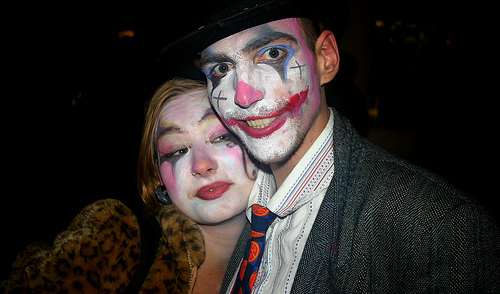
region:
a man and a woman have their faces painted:
[103, 11, 387, 228]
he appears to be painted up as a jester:
[180, 14, 334, 165]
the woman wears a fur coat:
[11, 188, 203, 293]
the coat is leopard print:
[16, 192, 206, 290]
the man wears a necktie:
[228, 203, 275, 292]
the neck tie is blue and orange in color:
[223, 206, 285, 292]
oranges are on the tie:
[235, 218, 278, 292]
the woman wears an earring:
[139, 177, 169, 214]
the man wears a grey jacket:
[293, 133, 492, 290]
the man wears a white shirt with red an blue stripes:
[247, 164, 327, 292]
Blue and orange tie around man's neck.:
[247, 206, 277, 282]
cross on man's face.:
[290, 55, 308, 83]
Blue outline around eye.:
[252, 23, 301, 83]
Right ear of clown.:
[313, 25, 345, 85]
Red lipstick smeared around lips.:
[235, 103, 303, 138]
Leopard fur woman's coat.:
[93, 196, 137, 263]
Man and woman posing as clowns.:
[137, 15, 352, 229]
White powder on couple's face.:
[149, 12, 313, 225]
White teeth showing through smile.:
[239, 109, 284, 136]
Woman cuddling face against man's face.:
[139, 15, 336, 227]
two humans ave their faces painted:
[1, 2, 498, 292]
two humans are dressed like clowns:
[1, 3, 498, 288]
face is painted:
[195, 16, 325, 163]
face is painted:
[148, 86, 253, 225]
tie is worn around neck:
[235, 204, 276, 293]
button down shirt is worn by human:
[228, 106, 343, 292]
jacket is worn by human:
[228, 115, 498, 292]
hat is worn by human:
[168, 0, 303, 64]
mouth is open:
[232, 111, 283, 132]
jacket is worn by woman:
[3, 189, 208, 292]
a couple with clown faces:
[19, 0, 482, 288]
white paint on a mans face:
[204, 15, 315, 171]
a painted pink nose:
[226, 79, 262, 114]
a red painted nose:
[228, 87, 315, 140]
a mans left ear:
[317, 32, 343, 79]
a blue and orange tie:
[231, 202, 281, 289]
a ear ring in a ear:
[151, 182, 173, 208]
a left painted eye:
[259, 38, 291, 74]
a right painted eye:
[210, 52, 236, 87]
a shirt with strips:
[288, 146, 333, 203]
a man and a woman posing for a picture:
[123, 3, 389, 268]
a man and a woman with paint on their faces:
[110, 13, 385, 254]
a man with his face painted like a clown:
[189, 14, 352, 172]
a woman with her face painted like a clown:
[138, 60, 265, 227]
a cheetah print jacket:
[17, 155, 244, 293]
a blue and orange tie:
[214, 186, 294, 290]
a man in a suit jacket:
[192, 8, 483, 278]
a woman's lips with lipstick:
[188, 181, 249, 202]